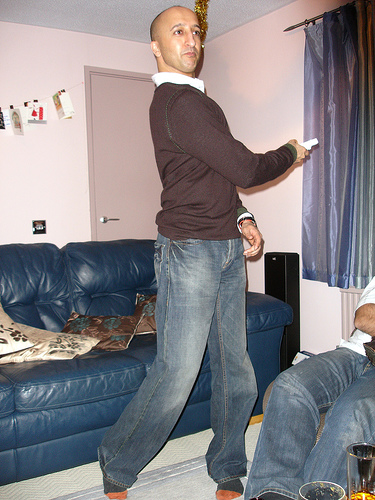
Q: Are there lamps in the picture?
A: No, there are no lamps.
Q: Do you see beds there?
A: No, there are no beds.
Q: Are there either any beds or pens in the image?
A: No, there are no beds or pens.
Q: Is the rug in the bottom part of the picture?
A: Yes, the rug is in the bottom of the image.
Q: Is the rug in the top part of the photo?
A: No, the rug is in the bottom of the image.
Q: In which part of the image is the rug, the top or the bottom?
A: The rug is in the bottom of the image.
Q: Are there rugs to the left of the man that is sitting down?
A: Yes, there is a rug to the left of the man.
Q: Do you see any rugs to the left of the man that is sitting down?
A: Yes, there is a rug to the left of the man.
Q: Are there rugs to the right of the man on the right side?
A: No, the rug is to the left of the man.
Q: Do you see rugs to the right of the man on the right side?
A: No, the rug is to the left of the man.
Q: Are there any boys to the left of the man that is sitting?
A: No, there is a rug to the left of the man.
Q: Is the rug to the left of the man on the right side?
A: Yes, the rug is to the left of the man.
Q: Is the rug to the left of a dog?
A: No, the rug is to the left of the man.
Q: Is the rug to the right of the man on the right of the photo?
A: No, the rug is to the left of the man.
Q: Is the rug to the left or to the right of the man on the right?
A: The rug is to the left of the man.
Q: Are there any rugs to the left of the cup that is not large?
A: Yes, there is a rug to the left of the cup.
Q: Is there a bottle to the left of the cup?
A: No, there is a rug to the left of the cup.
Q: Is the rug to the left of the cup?
A: Yes, the rug is to the left of the cup.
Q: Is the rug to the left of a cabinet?
A: No, the rug is to the left of the cup.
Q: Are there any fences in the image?
A: No, there are no fences.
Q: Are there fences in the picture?
A: No, there are no fences.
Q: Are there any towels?
A: No, there are no towels.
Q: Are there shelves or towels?
A: No, there are no towels or shelves.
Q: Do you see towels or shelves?
A: No, there are no towels or shelves.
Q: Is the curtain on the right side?
A: Yes, the curtain is on the right of the image.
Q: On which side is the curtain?
A: The curtain is on the right of the image.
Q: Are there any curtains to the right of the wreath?
A: Yes, there is a curtain to the right of the wreath.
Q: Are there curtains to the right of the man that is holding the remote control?
A: Yes, there is a curtain to the right of the man.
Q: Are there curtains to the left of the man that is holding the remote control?
A: No, the curtain is to the right of the man.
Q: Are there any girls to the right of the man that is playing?
A: No, there is a curtain to the right of the man.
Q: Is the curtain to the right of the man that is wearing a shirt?
A: Yes, the curtain is to the right of the man.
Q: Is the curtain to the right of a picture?
A: No, the curtain is to the right of the man.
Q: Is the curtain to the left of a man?
A: No, the curtain is to the right of a man.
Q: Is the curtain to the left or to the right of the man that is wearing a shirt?
A: The curtain is to the right of the man.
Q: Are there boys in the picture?
A: No, there are no boys.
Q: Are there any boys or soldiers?
A: No, there are no boys or soldiers.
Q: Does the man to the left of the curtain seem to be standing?
A: Yes, the man is standing.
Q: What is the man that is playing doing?
A: The man is standing.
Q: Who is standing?
A: The man is standing.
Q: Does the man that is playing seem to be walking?
A: No, the man is standing.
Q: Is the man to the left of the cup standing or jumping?
A: The man is standing.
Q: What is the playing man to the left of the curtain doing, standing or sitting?
A: The man is standing.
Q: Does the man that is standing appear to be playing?
A: Yes, the man is playing.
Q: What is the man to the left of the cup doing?
A: The man is playing.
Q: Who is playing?
A: The man is playing.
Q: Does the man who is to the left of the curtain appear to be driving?
A: No, the man is playing.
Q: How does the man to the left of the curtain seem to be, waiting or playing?
A: The man is playing.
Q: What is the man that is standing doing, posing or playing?
A: The man is playing.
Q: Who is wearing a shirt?
A: The man is wearing a shirt.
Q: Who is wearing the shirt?
A: The man is wearing a shirt.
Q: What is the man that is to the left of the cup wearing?
A: The man is wearing a shirt.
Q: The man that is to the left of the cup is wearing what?
A: The man is wearing a shirt.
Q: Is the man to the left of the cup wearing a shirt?
A: Yes, the man is wearing a shirt.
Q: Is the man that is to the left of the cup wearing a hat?
A: No, the man is wearing a shirt.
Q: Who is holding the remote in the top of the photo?
A: The man is holding the remote control.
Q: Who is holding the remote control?
A: The man is holding the remote control.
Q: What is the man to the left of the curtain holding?
A: The man is holding the remote.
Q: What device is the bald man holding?
A: The man is holding the remote.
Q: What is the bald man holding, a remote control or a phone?
A: The man is holding a remote control.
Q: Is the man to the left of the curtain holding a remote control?
A: Yes, the man is holding a remote control.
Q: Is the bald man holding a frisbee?
A: No, the man is holding a remote control.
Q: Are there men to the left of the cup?
A: Yes, there is a man to the left of the cup.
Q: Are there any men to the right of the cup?
A: No, the man is to the left of the cup.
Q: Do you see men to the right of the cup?
A: No, the man is to the left of the cup.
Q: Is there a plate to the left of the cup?
A: No, there is a man to the left of the cup.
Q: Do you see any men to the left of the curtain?
A: Yes, there is a man to the left of the curtain.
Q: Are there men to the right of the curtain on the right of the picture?
A: No, the man is to the left of the curtain.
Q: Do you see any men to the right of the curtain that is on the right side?
A: No, the man is to the left of the curtain.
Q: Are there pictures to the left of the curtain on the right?
A: No, there is a man to the left of the curtain.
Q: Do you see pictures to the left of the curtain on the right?
A: No, there is a man to the left of the curtain.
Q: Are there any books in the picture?
A: No, there are no books.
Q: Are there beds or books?
A: No, there are no books or beds.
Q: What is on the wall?
A: The card is on the wall.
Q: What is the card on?
A: The card is on the wall.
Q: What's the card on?
A: The card is on the wall.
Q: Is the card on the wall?
A: Yes, the card is on the wall.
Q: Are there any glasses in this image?
A: No, there are no glasses.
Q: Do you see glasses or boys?
A: No, there are no glasses or boys.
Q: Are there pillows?
A: Yes, there is a pillow.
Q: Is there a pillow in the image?
A: Yes, there is a pillow.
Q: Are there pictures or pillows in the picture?
A: Yes, there is a pillow.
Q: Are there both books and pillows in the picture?
A: No, there is a pillow but no books.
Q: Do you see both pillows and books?
A: No, there is a pillow but no books.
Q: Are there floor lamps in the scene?
A: No, there are no floor lamps.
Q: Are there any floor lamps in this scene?
A: No, there are no floor lamps.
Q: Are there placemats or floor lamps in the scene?
A: No, there are no floor lamps or placemats.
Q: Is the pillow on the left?
A: Yes, the pillow is on the left of the image.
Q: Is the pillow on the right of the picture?
A: No, the pillow is on the left of the image.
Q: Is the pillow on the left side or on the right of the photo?
A: The pillow is on the left of the image.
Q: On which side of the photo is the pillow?
A: The pillow is on the left of the image.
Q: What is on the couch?
A: The pillow is on the couch.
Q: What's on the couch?
A: The pillow is on the couch.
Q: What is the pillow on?
A: The pillow is on the couch.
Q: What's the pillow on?
A: The pillow is on the couch.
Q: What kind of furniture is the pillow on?
A: The pillow is on the couch.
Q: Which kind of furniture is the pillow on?
A: The pillow is on the couch.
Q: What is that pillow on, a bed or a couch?
A: The pillow is on a couch.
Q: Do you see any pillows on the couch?
A: Yes, there is a pillow on the couch.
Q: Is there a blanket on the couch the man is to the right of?
A: No, there is a pillow on the couch.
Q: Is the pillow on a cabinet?
A: No, the pillow is on the couch.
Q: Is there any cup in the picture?
A: Yes, there is a cup.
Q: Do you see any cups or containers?
A: Yes, there is a cup.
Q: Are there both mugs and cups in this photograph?
A: No, there is a cup but no mugs.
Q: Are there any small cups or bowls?
A: Yes, there is a small cup.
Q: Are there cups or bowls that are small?
A: Yes, the cup is small.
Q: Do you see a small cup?
A: Yes, there is a small cup.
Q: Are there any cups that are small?
A: Yes, there is a cup that is small.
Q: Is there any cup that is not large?
A: Yes, there is a small cup.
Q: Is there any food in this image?
A: No, there is no food.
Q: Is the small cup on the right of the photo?
A: Yes, the cup is on the right of the image.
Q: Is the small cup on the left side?
A: No, the cup is on the right of the image.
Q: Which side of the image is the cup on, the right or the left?
A: The cup is on the right of the image.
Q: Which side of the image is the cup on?
A: The cup is on the right of the image.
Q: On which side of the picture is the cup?
A: The cup is on the right of the image.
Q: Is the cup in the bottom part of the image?
A: Yes, the cup is in the bottom of the image.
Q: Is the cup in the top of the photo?
A: No, the cup is in the bottom of the image.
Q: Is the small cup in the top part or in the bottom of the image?
A: The cup is in the bottom of the image.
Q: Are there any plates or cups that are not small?
A: No, there is a cup but it is small.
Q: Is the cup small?
A: Yes, the cup is small.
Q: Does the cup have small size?
A: Yes, the cup is small.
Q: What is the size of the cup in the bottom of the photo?
A: The cup is small.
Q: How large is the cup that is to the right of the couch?
A: The cup is small.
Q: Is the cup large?
A: No, the cup is small.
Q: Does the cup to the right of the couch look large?
A: No, the cup is small.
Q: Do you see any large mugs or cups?
A: No, there is a cup but it is small.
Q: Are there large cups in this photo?
A: No, there is a cup but it is small.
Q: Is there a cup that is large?
A: No, there is a cup but it is small.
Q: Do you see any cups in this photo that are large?
A: No, there is a cup but it is small.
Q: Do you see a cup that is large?
A: No, there is a cup but it is small.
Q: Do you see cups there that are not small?
A: No, there is a cup but it is small.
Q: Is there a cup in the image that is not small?
A: No, there is a cup but it is small.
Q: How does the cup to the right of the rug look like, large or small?
A: The cup is small.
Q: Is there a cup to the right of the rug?
A: Yes, there is a cup to the right of the rug.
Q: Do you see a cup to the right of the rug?
A: Yes, there is a cup to the right of the rug.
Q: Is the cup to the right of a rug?
A: Yes, the cup is to the right of a rug.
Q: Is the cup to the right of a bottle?
A: No, the cup is to the right of a rug.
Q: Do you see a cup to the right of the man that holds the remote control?
A: Yes, there is a cup to the right of the man.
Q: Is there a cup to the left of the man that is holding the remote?
A: No, the cup is to the right of the man.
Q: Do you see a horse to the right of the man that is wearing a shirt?
A: No, there is a cup to the right of the man.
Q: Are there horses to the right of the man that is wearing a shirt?
A: No, there is a cup to the right of the man.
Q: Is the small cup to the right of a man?
A: Yes, the cup is to the right of a man.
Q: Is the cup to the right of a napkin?
A: No, the cup is to the right of a man.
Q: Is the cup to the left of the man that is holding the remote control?
A: No, the cup is to the right of the man.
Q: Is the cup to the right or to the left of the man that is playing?
A: The cup is to the right of the man.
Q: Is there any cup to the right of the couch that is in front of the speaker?
A: Yes, there is a cup to the right of the couch.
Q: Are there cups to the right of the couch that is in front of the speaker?
A: Yes, there is a cup to the right of the couch.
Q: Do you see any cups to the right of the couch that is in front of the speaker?
A: Yes, there is a cup to the right of the couch.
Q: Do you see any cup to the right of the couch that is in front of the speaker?
A: Yes, there is a cup to the right of the couch.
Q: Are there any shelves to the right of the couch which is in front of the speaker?
A: No, there is a cup to the right of the couch.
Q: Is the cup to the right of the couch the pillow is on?
A: Yes, the cup is to the right of the couch.